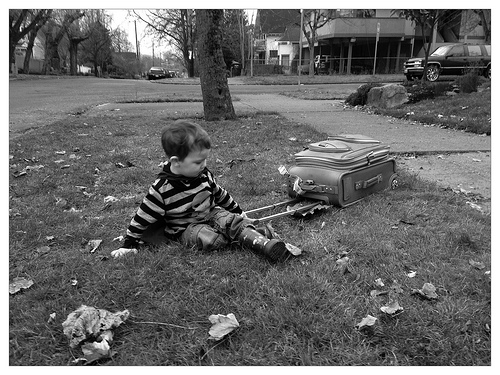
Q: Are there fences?
A: No, there are no fences.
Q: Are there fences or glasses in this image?
A: No, there are no fences or glasses.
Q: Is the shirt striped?
A: Yes, the shirt is striped.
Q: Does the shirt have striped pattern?
A: Yes, the shirt is striped.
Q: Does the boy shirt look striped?
A: Yes, the shirt is striped.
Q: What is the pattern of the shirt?
A: The shirt is striped.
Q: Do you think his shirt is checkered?
A: No, the shirt is striped.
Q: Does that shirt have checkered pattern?
A: No, the shirt is striped.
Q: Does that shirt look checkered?
A: No, the shirt is striped.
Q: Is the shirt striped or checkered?
A: The shirt is striped.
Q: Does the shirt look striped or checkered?
A: The shirt is striped.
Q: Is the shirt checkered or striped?
A: The shirt is striped.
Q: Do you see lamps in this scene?
A: No, there are no lamps.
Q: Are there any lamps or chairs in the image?
A: No, there are no lamps or chairs.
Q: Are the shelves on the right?
A: Yes, the shelves are on the right of the image.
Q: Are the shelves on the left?
A: No, the shelves are on the right of the image.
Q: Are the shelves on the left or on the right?
A: The shelves are on the right of the image.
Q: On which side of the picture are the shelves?
A: The shelves are on the right of the image.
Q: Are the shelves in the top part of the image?
A: Yes, the shelves are in the top of the image.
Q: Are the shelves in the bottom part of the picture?
A: No, the shelves are in the top of the image.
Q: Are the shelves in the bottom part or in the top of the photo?
A: The shelves are in the top of the image.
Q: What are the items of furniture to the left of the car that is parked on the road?
A: The pieces of furniture are shelves.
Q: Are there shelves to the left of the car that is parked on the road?
A: Yes, there are shelves to the left of the car.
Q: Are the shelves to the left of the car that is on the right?
A: Yes, the shelves are to the left of the car.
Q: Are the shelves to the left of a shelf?
A: No, the shelves are to the left of the car.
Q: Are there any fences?
A: No, there are no fences.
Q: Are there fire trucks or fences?
A: No, there are no fences or fire trucks.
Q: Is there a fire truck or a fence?
A: No, there are no fences or fire trucks.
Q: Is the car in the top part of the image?
A: Yes, the car is in the top of the image.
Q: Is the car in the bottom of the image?
A: No, the car is in the top of the image.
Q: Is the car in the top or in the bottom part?
A: The car is in the top of the image.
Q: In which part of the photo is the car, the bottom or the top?
A: The car is in the top of the image.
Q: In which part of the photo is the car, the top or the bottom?
A: The car is in the top of the image.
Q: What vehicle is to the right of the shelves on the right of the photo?
A: The vehicle is a car.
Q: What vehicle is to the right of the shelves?
A: The vehicle is a car.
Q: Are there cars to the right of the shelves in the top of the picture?
A: Yes, there is a car to the right of the shelves.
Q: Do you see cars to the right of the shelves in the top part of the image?
A: Yes, there is a car to the right of the shelves.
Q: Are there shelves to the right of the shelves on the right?
A: No, there is a car to the right of the shelves.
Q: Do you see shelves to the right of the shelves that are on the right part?
A: No, there is a car to the right of the shelves.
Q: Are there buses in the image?
A: No, there are no buses.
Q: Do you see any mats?
A: No, there are no mats.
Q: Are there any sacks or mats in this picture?
A: No, there are no mats or sacks.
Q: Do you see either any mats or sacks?
A: No, there are no mats or sacks.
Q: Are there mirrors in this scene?
A: No, there are no mirrors.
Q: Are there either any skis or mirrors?
A: No, there are no mirrors or skis.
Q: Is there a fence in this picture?
A: No, there are no fences.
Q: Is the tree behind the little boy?
A: Yes, the tree is behind the boy.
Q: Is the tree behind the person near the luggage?
A: Yes, the tree is behind the boy.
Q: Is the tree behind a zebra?
A: No, the tree is behind the boy.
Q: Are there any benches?
A: No, there are no benches.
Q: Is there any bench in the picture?
A: No, there are no benches.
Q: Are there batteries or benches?
A: No, there are no benches or batteries.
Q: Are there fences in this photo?
A: No, there are no fences.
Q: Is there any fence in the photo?
A: No, there are no fences.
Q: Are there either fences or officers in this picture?
A: No, there are no fences or officers.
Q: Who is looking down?
A: The boy is looking down.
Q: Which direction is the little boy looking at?
A: The boy is looking down.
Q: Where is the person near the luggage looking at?
A: The boy is looking down.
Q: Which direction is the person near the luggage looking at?
A: The boy is looking down.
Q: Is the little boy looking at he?
A: Yes, the boy is looking down.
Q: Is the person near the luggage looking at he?
A: Yes, the boy is looking down.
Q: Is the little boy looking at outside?
A: No, the boy is looking down.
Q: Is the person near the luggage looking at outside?
A: No, the boy is looking down.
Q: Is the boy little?
A: Yes, the boy is little.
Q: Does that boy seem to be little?
A: Yes, the boy is little.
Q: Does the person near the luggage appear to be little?
A: Yes, the boy is little.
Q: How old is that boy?
A: The boy is little.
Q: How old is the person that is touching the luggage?
A: The boy is little.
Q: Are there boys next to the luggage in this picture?
A: Yes, there is a boy next to the luggage.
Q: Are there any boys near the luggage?
A: Yes, there is a boy near the luggage.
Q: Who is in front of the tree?
A: The boy is in front of the tree.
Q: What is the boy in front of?
A: The boy is in front of the tree.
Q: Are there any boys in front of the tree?
A: Yes, there is a boy in front of the tree.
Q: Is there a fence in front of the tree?
A: No, there is a boy in front of the tree.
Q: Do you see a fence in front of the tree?
A: No, there is a boy in front of the tree.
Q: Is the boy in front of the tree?
A: Yes, the boy is in front of the tree.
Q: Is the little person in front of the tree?
A: Yes, the boy is in front of the tree.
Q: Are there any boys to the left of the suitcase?
A: Yes, there is a boy to the left of the suitcase.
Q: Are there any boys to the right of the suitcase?
A: No, the boy is to the left of the suitcase.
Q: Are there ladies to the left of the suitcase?
A: No, there is a boy to the left of the suitcase.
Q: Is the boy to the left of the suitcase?
A: Yes, the boy is to the left of the suitcase.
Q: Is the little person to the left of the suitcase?
A: Yes, the boy is to the left of the suitcase.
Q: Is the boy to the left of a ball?
A: No, the boy is to the left of the suitcase.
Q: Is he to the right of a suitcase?
A: No, the boy is to the left of a suitcase.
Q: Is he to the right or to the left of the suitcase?
A: The boy is to the left of the suitcase.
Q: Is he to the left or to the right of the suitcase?
A: The boy is to the left of the suitcase.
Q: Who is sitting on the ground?
A: The boy is sitting on the ground.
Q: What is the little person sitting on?
A: The boy is sitting on the ground.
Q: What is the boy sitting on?
A: The boy is sitting on the ground.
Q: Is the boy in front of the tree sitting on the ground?
A: Yes, the boy is sitting on the ground.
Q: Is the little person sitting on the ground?
A: Yes, the boy is sitting on the ground.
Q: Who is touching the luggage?
A: The boy is touching the luggage.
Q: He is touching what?
A: The boy is touching the luggage.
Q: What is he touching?
A: The boy is touching the luggage.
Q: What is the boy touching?
A: The boy is touching the luggage.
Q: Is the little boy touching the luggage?
A: Yes, the boy is touching the luggage.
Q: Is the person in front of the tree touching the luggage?
A: Yes, the boy is touching the luggage.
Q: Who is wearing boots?
A: The boy is wearing boots.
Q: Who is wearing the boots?
A: The boy is wearing boots.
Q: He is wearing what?
A: The boy is wearing boots.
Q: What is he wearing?
A: The boy is wearing boots.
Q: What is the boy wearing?
A: The boy is wearing boots.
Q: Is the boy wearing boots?
A: Yes, the boy is wearing boots.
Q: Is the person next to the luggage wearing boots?
A: Yes, the boy is wearing boots.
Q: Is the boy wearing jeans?
A: No, the boy is wearing boots.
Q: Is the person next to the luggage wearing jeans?
A: No, the boy is wearing boots.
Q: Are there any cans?
A: No, there are no cans.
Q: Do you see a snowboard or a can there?
A: No, there are no cans or snowboards.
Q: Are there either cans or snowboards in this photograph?
A: No, there are no cans or snowboards.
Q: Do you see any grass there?
A: Yes, there is grass.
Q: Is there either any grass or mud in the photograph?
A: Yes, there is grass.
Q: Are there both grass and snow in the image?
A: No, there is grass but no snow.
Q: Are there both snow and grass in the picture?
A: No, there is grass but no snow.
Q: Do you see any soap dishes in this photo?
A: No, there are no soap dishes.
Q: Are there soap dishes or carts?
A: No, there are no soap dishes or carts.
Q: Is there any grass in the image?
A: Yes, there is grass.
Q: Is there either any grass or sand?
A: Yes, there is grass.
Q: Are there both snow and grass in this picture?
A: No, there is grass but no snow.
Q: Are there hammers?
A: No, there are no hammers.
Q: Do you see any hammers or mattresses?
A: No, there are no hammers or mattresses.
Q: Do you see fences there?
A: No, there are no fences.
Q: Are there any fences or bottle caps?
A: No, there are no fences or bottle caps.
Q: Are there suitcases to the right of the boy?
A: Yes, there is a suitcase to the right of the boy.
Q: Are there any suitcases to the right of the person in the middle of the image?
A: Yes, there is a suitcase to the right of the boy.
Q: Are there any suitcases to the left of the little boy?
A: No, the suitcase is to the right of the boy.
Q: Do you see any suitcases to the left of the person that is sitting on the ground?
A: No, the suitcase is to the right of the boy.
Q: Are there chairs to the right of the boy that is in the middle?
A: No, there is a suitcase to the right of the boy.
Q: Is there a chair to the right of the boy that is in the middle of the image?
A: No, there is a suitcase to the right of the boy.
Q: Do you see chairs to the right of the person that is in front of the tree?
A: No, there is a suitcase to the right of the boy.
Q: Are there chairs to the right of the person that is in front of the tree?
A: No, there is a suitcase to the right of the boy.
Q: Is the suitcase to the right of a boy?
A: Yes, the suitcase is to the right of a boy.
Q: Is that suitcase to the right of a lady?
A: No, the suitcase is to the right of a boy.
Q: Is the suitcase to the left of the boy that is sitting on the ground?
A: No, the suitcase is to the right of the boy.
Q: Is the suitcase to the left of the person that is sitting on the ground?
A: No, the suitcase is to the right of the boy.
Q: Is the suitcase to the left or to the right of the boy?
A: The suitcase is to the right of the boy.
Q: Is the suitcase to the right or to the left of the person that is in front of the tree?
A: The suitcase is to the right of the boy.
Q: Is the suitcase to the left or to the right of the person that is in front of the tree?
A: The suitcase is to the right of the boy.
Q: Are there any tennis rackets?
A: No, there are no tennis rackets.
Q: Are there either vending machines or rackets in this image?
A: No, there are no rackets or vending machines.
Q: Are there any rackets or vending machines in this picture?
A: No, there are no rackets or vending machines.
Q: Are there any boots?
A: Yes, there are boots.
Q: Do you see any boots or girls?
A: Yes, there are boots.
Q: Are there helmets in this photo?
A: No, there are no helmets.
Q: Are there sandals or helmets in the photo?
A: No, there are no helmets or sandals.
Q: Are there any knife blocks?
A: No, there are no knife blocks.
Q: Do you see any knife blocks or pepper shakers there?
A: No, there are no knife blocks or pepper shakers.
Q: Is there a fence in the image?
A: No, there are no fences.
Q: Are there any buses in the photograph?
A: No, there are no buses.